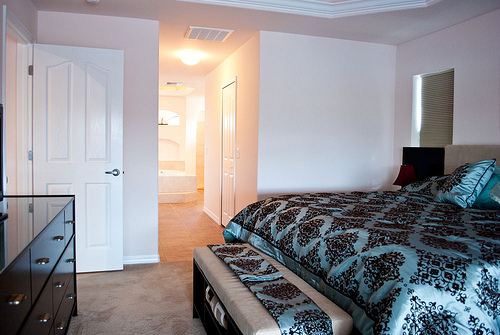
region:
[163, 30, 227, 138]
the lights are on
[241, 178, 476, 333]
the bed has a unique design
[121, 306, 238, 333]
the carpet has a footprint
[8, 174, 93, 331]
the dresser is brown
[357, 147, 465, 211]
the lamp is red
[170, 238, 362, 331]
there is a bench to sit down on in front of bed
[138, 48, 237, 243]
the bathroom has no door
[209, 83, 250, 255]
there is a closet in the hallway to the bathroom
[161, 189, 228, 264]
there is tiled floor in the bathroom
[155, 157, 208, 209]
the bath tub looks big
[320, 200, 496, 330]
a blue and black baroque pattern on a bedspread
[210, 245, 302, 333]
a blue and black runner along a bench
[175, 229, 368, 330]
a tan bench at the foot of the bed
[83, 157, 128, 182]
a silver door handle on a white door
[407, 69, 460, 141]
a window with white blinds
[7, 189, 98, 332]
a black dresser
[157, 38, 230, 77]
a bright light between the bedroom and bathroom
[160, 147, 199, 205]
a white bath tub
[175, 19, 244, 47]
a white vent on the ceiling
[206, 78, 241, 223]
a closet door in the hallway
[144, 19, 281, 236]
light in a hallway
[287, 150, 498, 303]
black and blue blanket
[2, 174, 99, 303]
brown and shiny dresser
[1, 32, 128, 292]
white door with metal handle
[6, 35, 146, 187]
door that is open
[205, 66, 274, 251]
door that is closed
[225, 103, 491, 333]
bed with decorative sheets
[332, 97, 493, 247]
shiny black and blue pillow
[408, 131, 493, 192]
black and blue pillow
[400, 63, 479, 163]
window blinds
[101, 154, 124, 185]
a door handle on a door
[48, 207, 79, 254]
a drawer in a dresser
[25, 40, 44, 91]
door hinge on a door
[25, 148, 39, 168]
a door hinge on a door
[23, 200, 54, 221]
reflection of a door and hinge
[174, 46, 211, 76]
a light on the ceiling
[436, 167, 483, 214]
a pillow on a bed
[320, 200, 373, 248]
light blue and dark blue fabric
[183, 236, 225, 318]
a chest at the end of a bed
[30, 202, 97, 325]
a set of dresser drawers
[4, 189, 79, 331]
wooden chest of drawers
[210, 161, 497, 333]
metallic blue comforter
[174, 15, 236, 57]
white metal air vent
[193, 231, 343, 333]
long ottoman with white cushion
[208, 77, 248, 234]
tall white closet door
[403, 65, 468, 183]
window with white blinds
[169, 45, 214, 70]
domed light embedded in ceiling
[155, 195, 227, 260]
brown hardwood floor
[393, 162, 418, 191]
red lamp shade